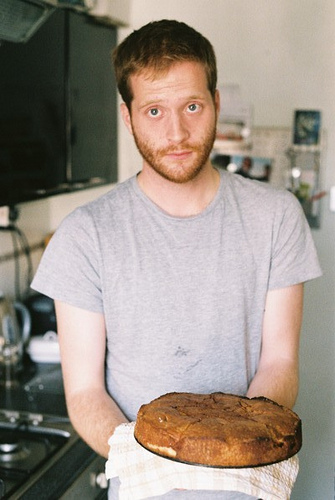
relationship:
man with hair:
[21, 21, 309, 479] [97, 15, 225, 107]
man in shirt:
[26, 17, 328, 498] [29, 166, 322, 422]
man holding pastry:
[26, 17, 328, 498] [128, 387, 306, 470]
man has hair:
[26, 17, 328, 498] [101, 16, 222, 98]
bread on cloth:
[142, 372, 333, 492] [104, 419, 299, 497]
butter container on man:
[24, 333, 66, 367] [26, 17, 328, 498]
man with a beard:
[26, 17, 328, 498] [118, 124, 241, 193]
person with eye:
[31, 19, 322, 498] [185, 102, 204, 113]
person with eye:
[31, 19, 322, 498] [144, 104, 164, 118]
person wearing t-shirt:
[31, 19, 322, 498] [29, 169, 321, 498]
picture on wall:
[281, 110, 324, 138] [224, 23, 332, 171]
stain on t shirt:
[174, 343, 187, 359] [30, 162, 324, 431]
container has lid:
[24, 329, 62, 362] [32, 328, 55, 345]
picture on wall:
[291, 105, 324, 146] [211, 3, 333, 195]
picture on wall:
[224, 150, 277, 182] [211, 3, 333, 195]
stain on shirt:
[172, 347, 190, 370] [32, 154, 328, 435]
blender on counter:
[0, 293, 33, 370] [2, 264, 315, 383]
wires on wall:
[3, 214, 34, 293] [4, 1, 116, 293]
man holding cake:
[26, 17, 328, 498] [134, 392, 301, 465]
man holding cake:
[26, 17, 328, 498] [126, 385, 311, 473]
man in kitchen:
[73, 166, 295, 363] [1, 2, 334, 496]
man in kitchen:
[52, 20, 303, 497] [1, 2, 334, 496]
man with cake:
[52, 20, 303, 497] [134, 392, 301, 465]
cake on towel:
[134, 392, 301, 465] [102, 421, 300, 498]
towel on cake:
[102, 421, 300, 498] [134, 392, 301, 465]